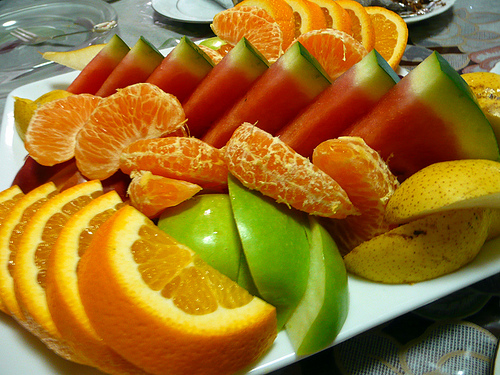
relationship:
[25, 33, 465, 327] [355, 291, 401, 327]
fruit on plate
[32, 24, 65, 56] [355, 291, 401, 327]
fork on plate